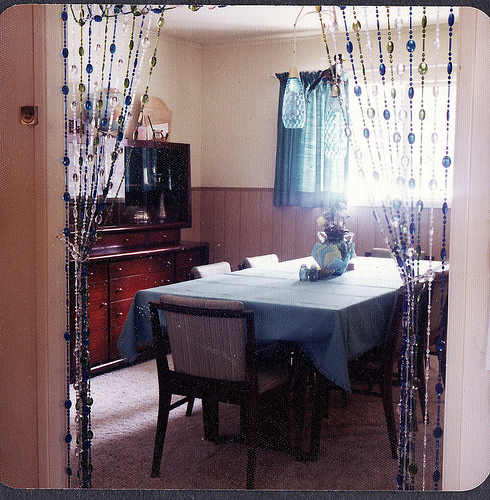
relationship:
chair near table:
[144, 304, 302, 482] [180, 237, 392, 416]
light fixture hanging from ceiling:
[256, 8, 325, 130] [110, 3, 469, 35]